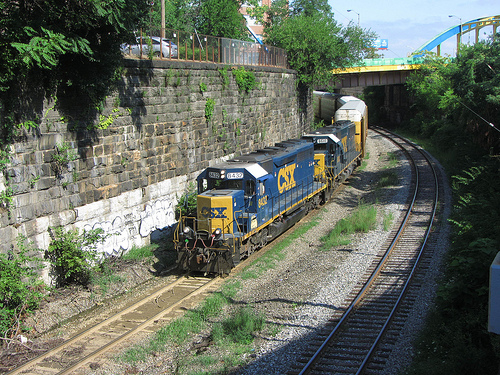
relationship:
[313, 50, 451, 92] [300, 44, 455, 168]
bridge next to wall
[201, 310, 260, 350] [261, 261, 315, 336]
grass in rocks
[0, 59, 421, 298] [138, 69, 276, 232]
wall made of rocks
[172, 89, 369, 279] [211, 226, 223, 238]
train has lights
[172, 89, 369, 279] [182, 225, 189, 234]
train has lights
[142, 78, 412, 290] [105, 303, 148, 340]
train on track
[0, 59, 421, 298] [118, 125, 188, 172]
wall made of brick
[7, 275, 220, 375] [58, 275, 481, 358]
tracks on ground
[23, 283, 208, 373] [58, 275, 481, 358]
tracks on ground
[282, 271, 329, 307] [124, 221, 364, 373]
gravel on ground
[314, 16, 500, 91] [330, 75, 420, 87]
bridge made of concrete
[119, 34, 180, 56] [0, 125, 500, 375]
car parked on ground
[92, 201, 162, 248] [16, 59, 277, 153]
graffiti on wall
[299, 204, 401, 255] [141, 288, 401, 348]
weeds between tracks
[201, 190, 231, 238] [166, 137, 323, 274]
nose of engine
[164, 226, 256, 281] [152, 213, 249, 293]
cattle guard on engine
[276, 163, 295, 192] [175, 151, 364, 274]
csx on engine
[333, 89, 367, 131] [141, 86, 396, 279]
roof of train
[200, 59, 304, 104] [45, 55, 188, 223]
plants growing wall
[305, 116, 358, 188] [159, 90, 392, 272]
engine on train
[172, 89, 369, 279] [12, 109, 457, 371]
train on track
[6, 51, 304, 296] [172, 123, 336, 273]
wall next to track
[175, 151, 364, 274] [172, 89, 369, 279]
engine on train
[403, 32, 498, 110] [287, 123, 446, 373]
leafy trees by track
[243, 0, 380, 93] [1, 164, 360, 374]
leafy trees by track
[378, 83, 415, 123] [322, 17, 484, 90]
tunnel for bridge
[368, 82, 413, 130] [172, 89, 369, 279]
tunnel for train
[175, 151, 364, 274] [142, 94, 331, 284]
engine of train